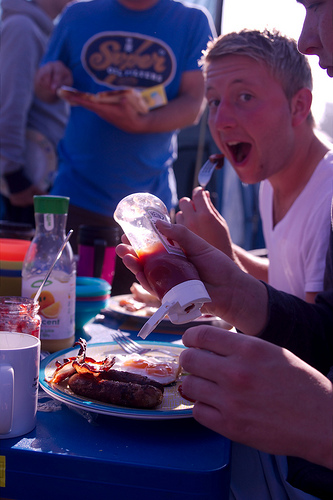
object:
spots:
[222, 372, 244, 430]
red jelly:
[0, 298, 44, 341]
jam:
[1, 296, 43, 338]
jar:
[0, 291, 41, 337]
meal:
[70, 372, 163, 410]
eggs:
[141, 355, 180, 387]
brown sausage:
[67, 371, 161, 406]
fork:
[197, 158, 218, 188]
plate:
[105, 290, 170, 323]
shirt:
[252, 145, 333, 308]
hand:
[170, 323, 331, 469]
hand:
[179, 188, 233, 256]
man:
[31, 1, 219, 254]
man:
[0, 1, 74, 221]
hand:
[56, 91, 144, 137]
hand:
[32, 63, 75, 107]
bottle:
[20, 188, 76, 359]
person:
[118, 1, 330, 500]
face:
[201, 51, 306, 183]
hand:
[113, 215, 230, 317]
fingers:
[180, 324, 249, 354]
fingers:
[122, 253, 144, 275]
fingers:
[193, 186, 210, 216]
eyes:
[237, 93, 252, 103]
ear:
[292, 88, 313, 127]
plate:
[31, 336, 244, 423]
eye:
[208, 99, 220, 107]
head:
[203, 27, 312, 180]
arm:
[54, 33, 215, 138]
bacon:
[36, 340, 110, 380]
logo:
[80, 30, 180, 95]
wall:
[183, 72, 227, 99]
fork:
[111, 330, 180, 358]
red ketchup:
[144, 253, 195, 297]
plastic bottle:
[110, 188, 211, 341]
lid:
[137, 277, 212, 344]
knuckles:
[232, 331, 258, 363]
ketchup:
[183, 302, 194, 312]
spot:
[254, 161, 267, 172]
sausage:
[71, 374, 161, 411]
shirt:
[38, 6, 217, 223]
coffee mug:
[0, 328, 42, 443]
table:
[0, 219, 251, 500]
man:
[172, 18, 333, 298]